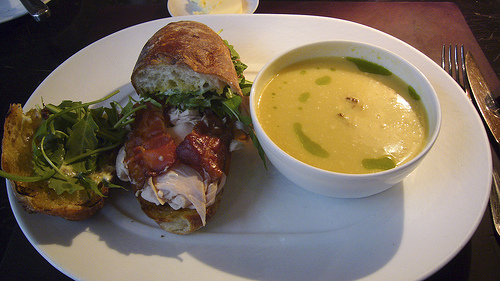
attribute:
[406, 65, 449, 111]
bowl — white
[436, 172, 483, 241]
plate — white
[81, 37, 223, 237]
sandwhich — brown, toasted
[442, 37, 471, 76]
fork — silver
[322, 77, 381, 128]
soup — yellow